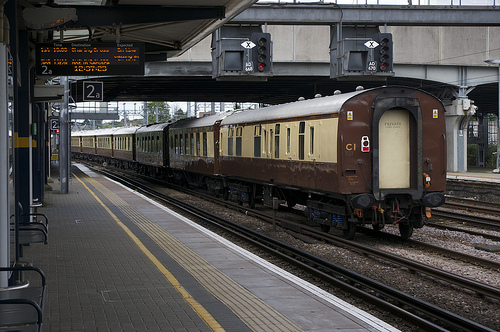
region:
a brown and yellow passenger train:
[68, 89, 448, 240]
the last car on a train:
[217, 81, 444, 239]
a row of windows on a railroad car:
[222, 118, 318, 160]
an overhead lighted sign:
[39, 40, 148, 77]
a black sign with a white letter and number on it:
[81, 78, 103, 104]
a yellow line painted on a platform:
[72, 170, 223, 325]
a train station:
[3, 1, 498, 328]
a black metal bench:
[2, 265, 44, 330]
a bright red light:
[252, 59, 269, 74]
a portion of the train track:
[408, 234, 498, 291]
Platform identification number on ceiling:
[75, 76, 108, 106]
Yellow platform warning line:
[64, 163, 229, 330]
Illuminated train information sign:
[30, 44, 145, 78]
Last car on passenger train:
[216, 82, 451, 233]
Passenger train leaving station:
[70, 80, 457, 210]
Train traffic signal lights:
[219, 33, 398, 81]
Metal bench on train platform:
[14, 209, 52, 256]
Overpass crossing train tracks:
[51, 30, 490, 179]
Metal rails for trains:
[105, 154, 499, 296]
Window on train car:
[293, 118, 308, 164]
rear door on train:
[373, 97, 424, 198]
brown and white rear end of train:
[342, 87, 450, 227]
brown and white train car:
[221, 89, 462, 211]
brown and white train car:
[164, 114, 221, 184]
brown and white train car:
[131, 119, 166, 179]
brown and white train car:
[109, 125, 134, 170]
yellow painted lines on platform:
[64, 160, 295, 329]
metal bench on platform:
[14, 201, 52, 253]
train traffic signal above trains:
[214, 32, 284, 79]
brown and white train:
[67, 90, 452, 237]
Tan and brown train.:
[82, 86, 445, 204]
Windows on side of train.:
[127, 122, 314, 159]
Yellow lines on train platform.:
[72, 171, 247, 329]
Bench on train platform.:
[0, 251, 52, 327]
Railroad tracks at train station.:
[380, 171, 495, 322]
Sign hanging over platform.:
[42, 42, 144, 71]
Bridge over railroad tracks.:
[149, 1, 499, 91]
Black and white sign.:
[79, 80, 105, 103]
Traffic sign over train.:
[222, 31, 275, 80]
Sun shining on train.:
[77, 115, 132, 151]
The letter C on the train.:
[347, 140, 353, 152]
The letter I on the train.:
[350, 139, 360, 151]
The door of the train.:
[376, 112, 412, 197]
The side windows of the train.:
[71, 121, 332, 172]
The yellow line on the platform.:
[68, 164, 190, 329]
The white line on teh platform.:
[145, 175, 392, 324]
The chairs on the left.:
[7, 187, 54, 330]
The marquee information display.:
[34, 42, 141, 68]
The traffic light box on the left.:
[210, 25, 274, 82]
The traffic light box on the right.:
[333, 31, 400, 83]